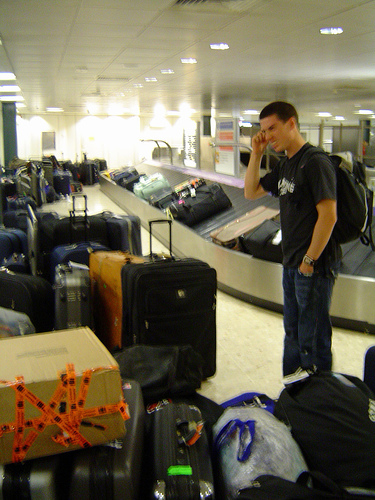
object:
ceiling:
[121, 31, 193, 83]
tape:
[0, 362, 130, 463]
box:
[0, 324, 128, 466]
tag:
[166, 464, 193, 476]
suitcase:
[154, 401, 215, 500]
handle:
[148, 219, 172, 261]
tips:
[153, 479, 166, 500]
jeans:
[280, 270, 334, 374]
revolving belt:
[86, 247, 156, 350]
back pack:
[327, 149, 375, 253]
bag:
[120, 218, 218, 378]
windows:
[0, 114, 141, 197]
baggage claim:
[239, 218, 283, 264]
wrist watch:
[303, 255, 315, 267]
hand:
[299, 257, 314, 277]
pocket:
[292, 271, 313, 313]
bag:
[208, 391, 314, 498]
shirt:
[258, 142, 342, 271]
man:
[242, 100, 343, 371]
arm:
[244, 155, 275, 201]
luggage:
[167, 174, 232, 229]